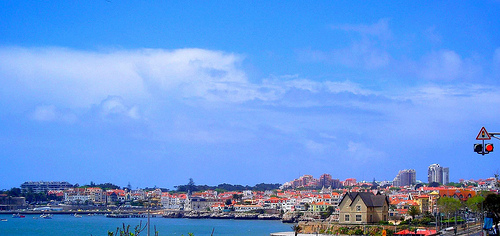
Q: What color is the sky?
A: Blue.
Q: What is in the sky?
A: Clouds.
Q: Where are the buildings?
A: On the shoreline.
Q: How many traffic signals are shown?
A: One.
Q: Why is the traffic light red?
A: To stop traffic.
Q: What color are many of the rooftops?
A: Red.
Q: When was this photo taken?
A: Daytime.